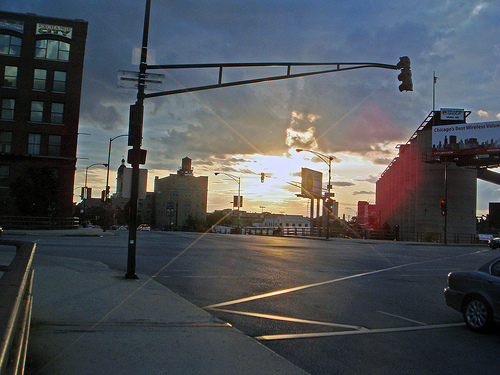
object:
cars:
[110, 224, 119, 232]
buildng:
[1, 10, 89, 230]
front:
[0, 10, 91, 231]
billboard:
[294, 166, 325, 201]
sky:
[0, 2, 500, 217]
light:
[393, 80, 413, 95]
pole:
[117, 0, 156, 278]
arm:
[143, 58, 395, 73]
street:
[114, 226, 499, 375]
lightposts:
[213, 171, 245, 233]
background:
[0, 0, 499, 375]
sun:
[234, 124, 349, 204]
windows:
[31, 68, 51, 81]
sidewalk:
[29, 239, 314, 374]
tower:
[177, 154, 192, 176]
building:
[153, 154, 208, 232]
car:
[135, 222, 149, 234]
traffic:
[433, 170, 452, 244]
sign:
[230, 194, 237, 211]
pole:
[426, 71, 436, 116]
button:
[126, 237, 135, 247]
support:
[117, 105, 154, 281]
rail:
[394, 111, 433, 161]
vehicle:
[443, 254, 498, 336]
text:
[431, 120, 498, 135]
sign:
[427, 118, 496, 159]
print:
[428, 119, 499, 158]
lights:
[146, 227, 151, 230]